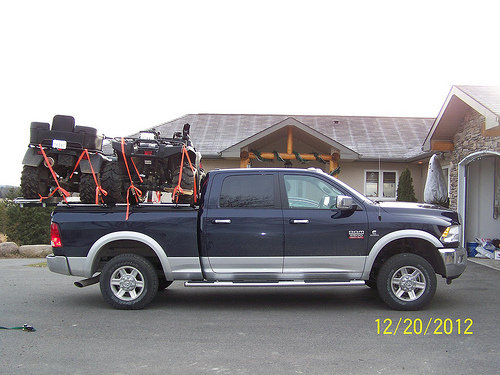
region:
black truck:
[61, 175, 476, 316]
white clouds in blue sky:
[188, 42, 245, 90]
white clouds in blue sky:
[418, 21, 483, 71]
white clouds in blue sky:
[387, 32, 412, 67]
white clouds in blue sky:
[290, 3, 341, 90]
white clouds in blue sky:
[208, 5, 272, 86]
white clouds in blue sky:
[141, 2, 182, 59]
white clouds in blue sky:
[61, 25, 132, 75]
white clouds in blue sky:
[110, 29, 180, 86]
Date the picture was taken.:
[372, 305, 478, 347]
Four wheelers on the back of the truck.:
[21, 113, 204, 205]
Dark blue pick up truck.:
[55, 170, 471, 312]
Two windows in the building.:
[358, 164, 407, 201]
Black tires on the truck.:
[95, 245, 159, 320]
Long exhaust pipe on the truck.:
[70, 266, 106, 297]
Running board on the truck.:
[175, 273, 371, 300]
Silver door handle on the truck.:
[286, 210, 326, 234]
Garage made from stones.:
[445, 107, 485, 166]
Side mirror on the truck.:
[325, 192, 367, 212]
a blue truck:
[37, 162, 472, 314]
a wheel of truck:
[373, 250, 438, 314]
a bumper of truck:
[438, 245, 470, 281]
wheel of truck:
[373, 249, 441, 314]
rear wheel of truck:
[95, 249, 159, 312]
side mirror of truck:
[333, 190, 355, 213]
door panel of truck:
[280, 171, 369, 277]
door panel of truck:
[206, 170, 285, 275]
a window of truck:
[283, 172, 337, 212]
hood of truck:
[377, 197, 456, 214]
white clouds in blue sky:
[5, 38, 29, 58]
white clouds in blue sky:
[294, 25, 346, 60]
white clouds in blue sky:
[268, 6, 316, 58]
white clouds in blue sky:
[174, 8, 209, 53]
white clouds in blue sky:
[190, 16, 257, 77]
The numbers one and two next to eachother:
[371, 318, 396, 342]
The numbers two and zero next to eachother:
[397, 319, 424, 343]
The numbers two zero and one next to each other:
[434, 318, 461, 336]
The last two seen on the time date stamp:
[464, 316, 476, 336]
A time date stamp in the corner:
[367, 315, 481, 345]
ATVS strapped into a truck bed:
[31, 113, 193, 211]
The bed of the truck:
[58, 201, 202, 295]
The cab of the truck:
[204, 172, 364, 289]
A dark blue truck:
[37, 123, 444, 323]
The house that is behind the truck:
[168, 109, 483, 249]